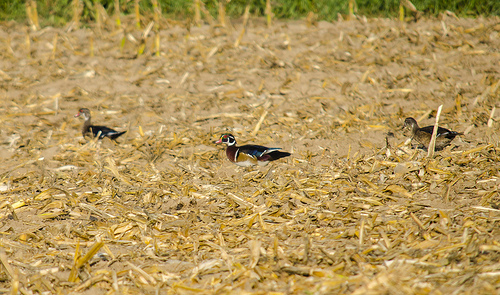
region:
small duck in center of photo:
[194, 118, 294, 185]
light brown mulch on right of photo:
[385, 196, 444, 257]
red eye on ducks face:
[222, 130, 229, 145]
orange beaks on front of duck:
[203, 132, 227, 151]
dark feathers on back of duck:
[94, 117, 121, 153]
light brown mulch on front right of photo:
[38, 227, 105, 278]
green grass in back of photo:
[202, 5, 282, 22]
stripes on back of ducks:
[218, 127, 265, 169]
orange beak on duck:
[68, 109, 84, 121]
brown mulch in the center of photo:
[294, 45, 364, 105]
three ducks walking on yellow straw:
[66, 98, 471, 181]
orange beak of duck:
[211, 135, 223, 147]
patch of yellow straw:
[108, 35, 299, 102]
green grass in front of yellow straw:
[5, 0, 499, 35]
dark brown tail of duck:
[266, 145, 293, 163]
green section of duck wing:
[248, 148, 265, 159]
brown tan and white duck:
[388, 110, 468, 152]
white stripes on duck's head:
[221, 132, 237, 146]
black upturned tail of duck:
[113, 123, 132, 138]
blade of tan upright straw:
[430, 100, 449, 160]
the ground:
[35, 167, 494, 277]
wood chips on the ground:
[50, 194, 448, 279]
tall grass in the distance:
[49, 0, 469, 35]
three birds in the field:
[33, 89, 498, 206]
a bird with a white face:
[76, 107, 128, 142]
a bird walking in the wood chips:
[215, 129, 289, 173]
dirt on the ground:
[138, 69, 190, 104]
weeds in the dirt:
[112, 10, 183, 61]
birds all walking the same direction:
[76, 100, 462, 165]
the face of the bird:
[402, 116, 414, 131]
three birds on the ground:
[61, 92, 461, 166]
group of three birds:
[68, 97, 463, 177]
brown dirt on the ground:
[7, 21, 492, 293]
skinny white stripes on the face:
[226, 133, 238, 146]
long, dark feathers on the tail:
[266, 147, 295, 160]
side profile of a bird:
[391, 109, 461, 151]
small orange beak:
[213, 136, 221, 146]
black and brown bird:
[395, 111, 465, 155]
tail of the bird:
[116, 124, 133, 136]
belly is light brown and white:
[236, 153, 258, 168]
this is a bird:
[199, 114, 300, 196]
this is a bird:
[386, 89, 476, 190]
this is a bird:
[64, 97, 121, 159]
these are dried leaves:
[164, 198, 246, 277]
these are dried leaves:
[280, 225, 387, 290]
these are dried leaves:
[92, 160, 174, 251]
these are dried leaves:
[309, 149, 434, 268]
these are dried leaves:
[293, 249, 371, 280]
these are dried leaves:
[284, 40, 369, 122]